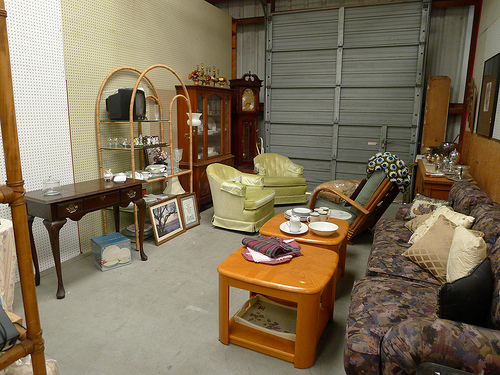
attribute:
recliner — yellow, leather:
[250, 149, 311, 205]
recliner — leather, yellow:
[204, 160, 276, 234]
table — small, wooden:
[216, 231, 333, 350]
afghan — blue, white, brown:
[363, 150, 420, 193]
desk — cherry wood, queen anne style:
[49, 176, 174, 277]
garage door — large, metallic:
[263, 5, 426, 200]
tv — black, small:
[104, 86, 146, 121]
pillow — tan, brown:
[445, 226, 487, 283]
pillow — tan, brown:
[435, 255, 496, 328]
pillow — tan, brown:
[402, 212, 484, 282]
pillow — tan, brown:
[406, 202, 473, 244]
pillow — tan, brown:
[405, 210, 431, 231]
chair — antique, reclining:
[288, 121, 435, 283]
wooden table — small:
[255, 206, 352, 289]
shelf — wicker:
[92, 58, 202, 256]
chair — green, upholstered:
[205, 158, 276, 236]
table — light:
[259, 208, 349, 288]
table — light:
[217, 240, 337, 369]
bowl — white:
[307, 220, 338, 235]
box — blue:
[90, 230, 131, 272]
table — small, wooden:
[24, 176, 146, 299]